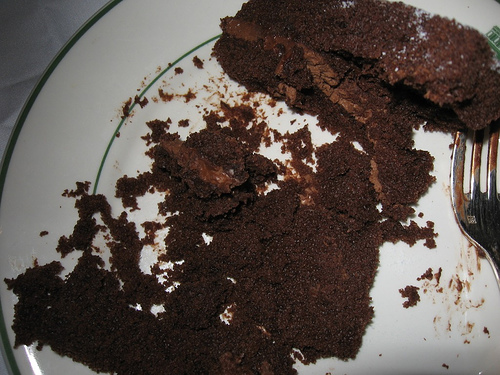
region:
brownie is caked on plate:
[5, 6, 482, 360]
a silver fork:
[451, 126, 498, 304]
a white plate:
[10, 5, 492, 365]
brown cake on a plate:
[14, 3, 496, 373]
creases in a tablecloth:
[10, 19, 97, 101]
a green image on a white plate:
[487, 22, 498, 70]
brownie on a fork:
[445, 128, 497, 228]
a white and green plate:
[7, 3, 497, 373]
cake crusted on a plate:
[8, 2, 493, 373]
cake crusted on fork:
[454, 135, 498, 222]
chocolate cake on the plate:
[162, 72, 399, 327]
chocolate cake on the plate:
[206, 20, 446, 283]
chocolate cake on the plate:
[147, 70, 452, 356]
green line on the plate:
[72, 78, 177, 248]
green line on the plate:
[22, 50, 205, 272]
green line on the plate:
[53, 71, 218, 302]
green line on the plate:
[39, 32, 231, 246]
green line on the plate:
[22, 74, 237, 290]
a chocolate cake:
[61, 7, 498, 369]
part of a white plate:
[24, 53, 114, 239]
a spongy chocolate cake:
[151, 109, 376, 353]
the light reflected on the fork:
[450, 161, 489, 206]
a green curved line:
[90, 79, 140, 191]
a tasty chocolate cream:
[161, 138, 236, 195]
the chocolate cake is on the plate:
[5, 4, 493, 365]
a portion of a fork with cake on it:
[447, 120, 498, 285]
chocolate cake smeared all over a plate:
[22, 6, 494, 372]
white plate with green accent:
[68, 29, 193, 124]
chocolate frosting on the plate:
[149, 122, 240, 196]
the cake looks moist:
[242, 172, 364, 331]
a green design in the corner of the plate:
[477, 19, 499, 64]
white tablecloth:
[7, 9, 49, 68]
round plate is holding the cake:
[33, 22, 195, 197]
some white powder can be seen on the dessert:
[396, 5, 443, 55]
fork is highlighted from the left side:
[439, 127, 499, 220]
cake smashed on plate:
[40, 256, 250, 369]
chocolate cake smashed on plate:
[15, 250, 196, 370]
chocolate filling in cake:
[161, 125, 231, 191]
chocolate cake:
[28, 270, 173, 365]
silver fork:
[451, 135, 498, 246]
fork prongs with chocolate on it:
[451, 132, 491, 224]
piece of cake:
[229, 2, 461, 182]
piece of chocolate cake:
[231, 13, 491, 126]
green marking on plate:
[101, 57, 163, 177]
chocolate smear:
[458, 254, 484, 346]